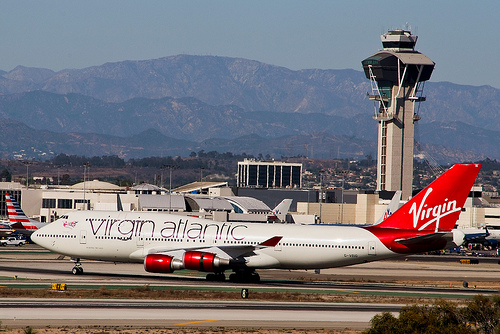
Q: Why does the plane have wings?
A: To fly.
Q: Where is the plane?
A: At an airport.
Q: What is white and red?
A: Plane.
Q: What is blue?
A: Sky.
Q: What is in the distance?
A: Mountains.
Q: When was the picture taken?
A: Daytime.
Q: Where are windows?
A: On a plane.